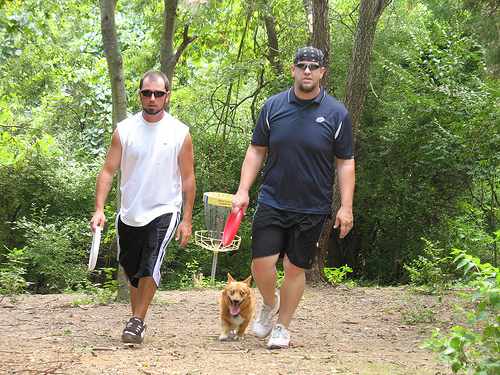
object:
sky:
[431, 108, 450, 120]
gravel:
[1, 287, 458, 372]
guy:
[229, 48, 358, 347]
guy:
[88, 69, 195, 345]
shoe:
[267, 326, 290, 349]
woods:
[104, 31, 124, 78]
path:
[14, 282, 463, 362]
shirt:
[102, 109, 192, 223]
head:
[294, 47, 327, 92]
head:
[141, 70, 170, 114]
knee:
[282, 255, 310, 274]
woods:
[358, 135, 371, 259]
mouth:
[227, 295, 247, 320]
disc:
[221, 200, 246, 244]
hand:
[332, 205, 352, 235]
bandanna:
[295, 47, 326, 61]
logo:
[317, 116, 328, 124]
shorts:
[252, 204, 325, 269]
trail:
[2, 285, 497, 374]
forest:
[0, 2, 496, 279]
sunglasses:
[140, 90, 165, 96]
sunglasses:
[293, 63, 321, 68]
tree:
[307, 0, 393, 286]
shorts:
[113, 214, 183, 283]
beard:
[140, 105, 162, 113]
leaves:
[408, 266, 417, 275]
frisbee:
[86, 225, 103, 276]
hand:
[88, 208, 108, 233]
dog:
[219, 273, 253, 342]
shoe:
[120, 315, 150, 347]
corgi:
[217, 272, 253, 340]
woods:
[354, 88, 488, 285]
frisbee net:
[194, 191, 240, 249]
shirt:
[257, 93, 360, 226]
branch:
[348, 0, 360, 31]